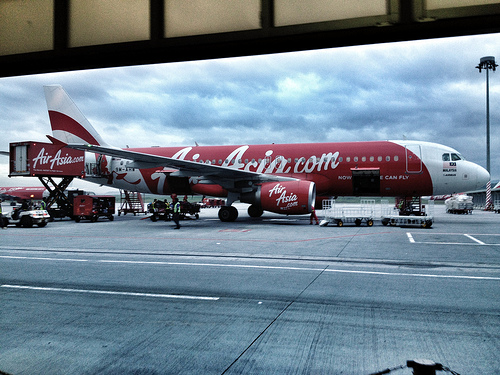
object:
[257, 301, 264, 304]
spot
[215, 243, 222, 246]
mark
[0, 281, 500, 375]
pavement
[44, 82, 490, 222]
plane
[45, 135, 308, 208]
wing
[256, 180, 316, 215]
engine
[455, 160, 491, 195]
nose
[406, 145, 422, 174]
door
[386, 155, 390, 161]
windows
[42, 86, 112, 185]
tail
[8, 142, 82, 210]
lift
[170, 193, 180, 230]
man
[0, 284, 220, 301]
line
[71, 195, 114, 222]
cart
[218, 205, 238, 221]
wheels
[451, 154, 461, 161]
windshield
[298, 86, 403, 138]
clouds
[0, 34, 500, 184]
sky